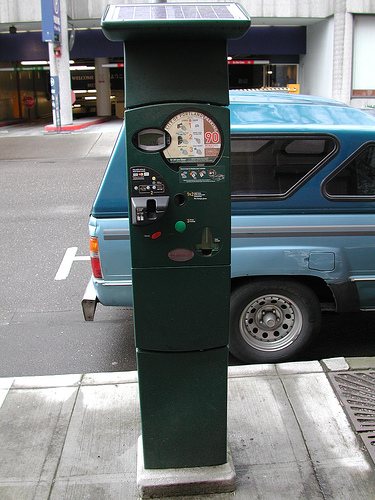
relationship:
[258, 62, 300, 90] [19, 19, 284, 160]
window on building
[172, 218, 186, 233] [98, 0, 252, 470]
button built into parking meter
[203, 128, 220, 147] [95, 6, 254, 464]
number 90 on a meter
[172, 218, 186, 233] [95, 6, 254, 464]
button on a meter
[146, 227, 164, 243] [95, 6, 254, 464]
button on a meter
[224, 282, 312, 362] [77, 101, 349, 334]
tire of a van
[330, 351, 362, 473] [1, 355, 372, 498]
plate on sidewalk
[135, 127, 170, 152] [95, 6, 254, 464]
display on meter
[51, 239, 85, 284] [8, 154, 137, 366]
line in road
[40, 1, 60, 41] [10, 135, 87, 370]
sign across street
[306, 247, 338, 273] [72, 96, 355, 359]
cover on side of truck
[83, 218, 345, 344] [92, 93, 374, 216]
truck with camper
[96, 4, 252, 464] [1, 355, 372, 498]
post on sidewalk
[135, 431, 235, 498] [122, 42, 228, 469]
base of post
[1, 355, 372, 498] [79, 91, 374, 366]
sidewalk next to truck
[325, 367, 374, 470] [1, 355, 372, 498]
grate in sidewalk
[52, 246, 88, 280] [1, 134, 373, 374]
lines painted on street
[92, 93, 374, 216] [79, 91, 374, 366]
camper on truck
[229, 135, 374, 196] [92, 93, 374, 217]
windows in camper shell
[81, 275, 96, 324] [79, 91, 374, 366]
bumper on truck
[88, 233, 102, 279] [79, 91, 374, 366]
brake light on truck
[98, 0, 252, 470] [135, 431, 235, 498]
parking meter on base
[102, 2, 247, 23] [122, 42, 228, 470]
solar panel on parking meter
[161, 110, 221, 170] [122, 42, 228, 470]
instructions on parking meter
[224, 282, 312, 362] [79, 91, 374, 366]
tire on side of truck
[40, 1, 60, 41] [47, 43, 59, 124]
sign on pole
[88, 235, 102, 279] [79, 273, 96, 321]
lights over bumper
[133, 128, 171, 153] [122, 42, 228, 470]
display of parking meter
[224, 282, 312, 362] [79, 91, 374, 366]
tire on a truck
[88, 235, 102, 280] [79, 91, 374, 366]
tail light on a truck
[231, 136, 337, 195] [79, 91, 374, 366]
window on a truck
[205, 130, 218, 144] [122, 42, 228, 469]
90 written on post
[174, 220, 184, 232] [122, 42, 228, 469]
button on post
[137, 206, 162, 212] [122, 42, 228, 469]
slot on post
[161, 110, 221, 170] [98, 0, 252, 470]
instructions on parking meter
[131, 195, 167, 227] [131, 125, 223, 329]
credit card slot on a parking meter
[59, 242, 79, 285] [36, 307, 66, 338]
line painted on pavement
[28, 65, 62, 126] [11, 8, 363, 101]
window attached to buildiing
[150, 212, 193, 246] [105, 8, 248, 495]
button on meter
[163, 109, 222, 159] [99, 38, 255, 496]
sticker telling meter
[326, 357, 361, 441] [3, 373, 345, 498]
drain on sidewalk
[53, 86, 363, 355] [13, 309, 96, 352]
car on street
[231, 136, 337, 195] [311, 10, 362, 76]
window on building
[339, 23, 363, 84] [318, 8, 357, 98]
window on building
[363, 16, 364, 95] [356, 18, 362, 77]
window on building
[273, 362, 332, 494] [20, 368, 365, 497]
crack in sidewalk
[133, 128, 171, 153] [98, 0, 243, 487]
display on a meter